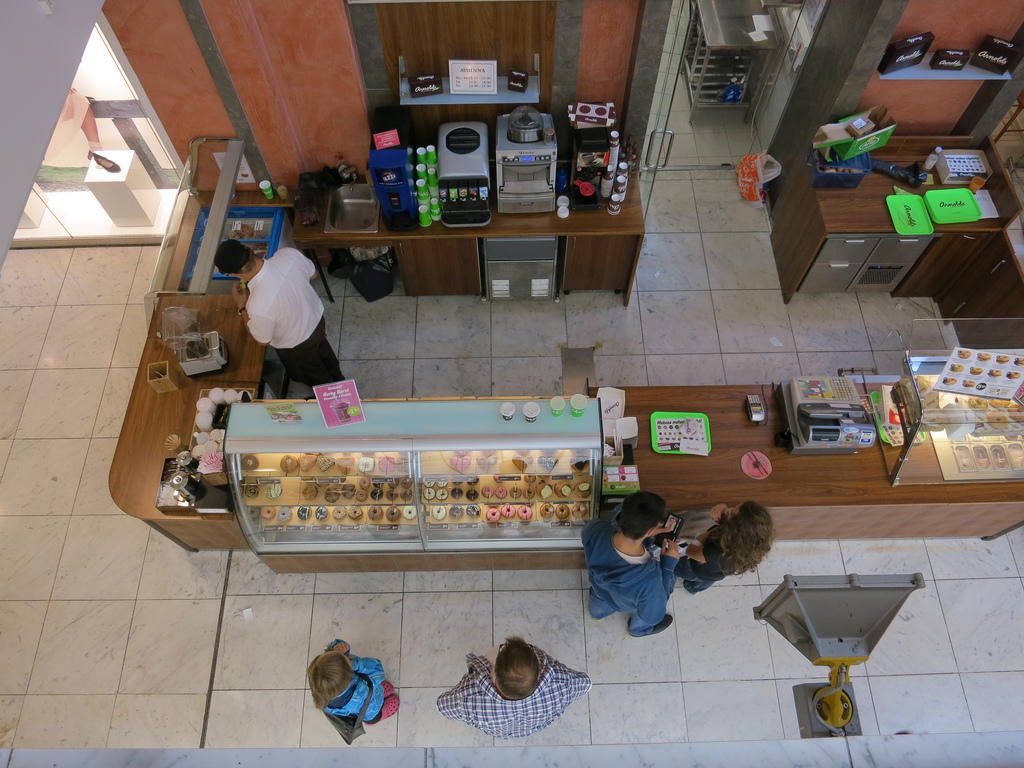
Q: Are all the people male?
A: No, they are both male and female.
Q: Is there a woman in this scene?
A: Yes, there is a woman.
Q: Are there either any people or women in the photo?
A: Yes, there is a woman.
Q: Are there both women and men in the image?
A: Yes, there are both a woman and a man.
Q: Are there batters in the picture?
A: No, there are no batters.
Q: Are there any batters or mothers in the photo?
A: No, there are no batters or mothers.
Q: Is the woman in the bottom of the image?
A: Yes, the woman is in the bottom of the image.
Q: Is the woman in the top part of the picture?
A: No, the woman is in the bottom of the image.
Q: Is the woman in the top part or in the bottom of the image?
A: The woman is in the bottom of the image.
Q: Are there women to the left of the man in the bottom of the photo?
A: Yes, there is a woman to the left of the man.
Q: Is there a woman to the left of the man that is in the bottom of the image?
A: Yes, there is a woman to the left of the man.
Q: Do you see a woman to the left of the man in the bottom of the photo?
A: Yes, there is a woman to the left of the man.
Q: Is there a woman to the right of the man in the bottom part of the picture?
A: No, the woman is to the left of the man.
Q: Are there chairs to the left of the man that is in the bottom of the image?
A: No, there is a woman to the left of the man.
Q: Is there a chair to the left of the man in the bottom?
A: No, there is a woman to the left of the man.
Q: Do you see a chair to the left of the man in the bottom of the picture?
A: No, there is a woman to the left of the man.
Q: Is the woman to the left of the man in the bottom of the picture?
A: Yes, the woman is to the left of the man.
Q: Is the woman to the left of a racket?
A: No, the woman is to the left of the man.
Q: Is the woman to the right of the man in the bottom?
A: No, the woman is to the left of the man.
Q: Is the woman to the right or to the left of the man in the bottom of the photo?
A: The woman is to the left of the man.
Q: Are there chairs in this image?
A: No, there are no chairs.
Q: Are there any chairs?
A: No, there are no chairs.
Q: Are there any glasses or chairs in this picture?
A: No, there are no chairs or glasses.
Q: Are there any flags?
A: No, there are no flags.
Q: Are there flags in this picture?
A: No, there are no flags.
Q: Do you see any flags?
A: No, there are no flags.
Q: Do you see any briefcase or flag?
A: No, there are no flags or briefcases.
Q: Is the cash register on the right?
A: Yes, the cash register is on the right of the image.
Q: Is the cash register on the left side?
A: No, the cash register is on the right of the image.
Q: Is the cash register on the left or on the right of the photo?
A: The cash register is on the right of the image.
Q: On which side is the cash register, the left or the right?
A: The cash register is on the right of the image.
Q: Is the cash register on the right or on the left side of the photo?
A: The cash register is on the right of the image.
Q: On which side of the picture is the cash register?
A: The cash register is on the right of the image.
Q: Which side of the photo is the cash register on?
A: The cash register is on the right of the image.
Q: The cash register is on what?
A: The cash register is on the counter.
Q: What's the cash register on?
A: The cash register is on the counter.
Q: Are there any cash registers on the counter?
A: Yes, there is a cash register on the counter.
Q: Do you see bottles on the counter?
A: No, there is a cash register on the counter.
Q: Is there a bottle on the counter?
A: No, there is a cash register on the counter.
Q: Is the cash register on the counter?
A: Yes, the cash register is on the counter.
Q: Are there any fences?
A: No, there are no fences.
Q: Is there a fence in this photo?
A: No, there are no fences.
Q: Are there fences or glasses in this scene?
A: No, there are no fences or glasses.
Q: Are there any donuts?
A: Yes, there are donuts.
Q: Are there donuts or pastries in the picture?
A: Yes, there are donuts.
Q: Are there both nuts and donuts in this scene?
A: No, there are donuts but no nuts.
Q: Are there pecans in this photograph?
A: No, there are no pecans.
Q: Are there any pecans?
A: No, there are no pecans.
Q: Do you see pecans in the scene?
A: No, there are no pecans.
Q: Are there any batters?
A: No, there are no batters.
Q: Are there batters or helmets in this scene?
A: No, there are no batters or helmets.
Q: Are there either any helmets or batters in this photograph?
A: No, there are no batters or helmets.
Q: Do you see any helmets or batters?
A: No, there are no batters or helmets.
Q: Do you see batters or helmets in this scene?
A: No, there are no batters or helmets.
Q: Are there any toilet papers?
A: No, there are no toilet papers.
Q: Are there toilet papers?
A: No, there are no toilet papers.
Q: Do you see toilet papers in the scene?
A: No, there are no toilet papers.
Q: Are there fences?
A: No, there are no fences.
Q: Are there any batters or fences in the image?
A: No, there are no fences or batters.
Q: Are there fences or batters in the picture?
A: No, there are no fences or batters.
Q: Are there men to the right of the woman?
A: Yes, there is a man to the right of the woman.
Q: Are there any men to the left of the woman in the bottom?
A: No, the man is to the right of the woman.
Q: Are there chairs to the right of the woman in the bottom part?
A: No, there is a man to the right of the woman.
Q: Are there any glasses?
A: No, there are no glasses.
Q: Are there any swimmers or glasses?
A: No, there are no glasses or swimmers.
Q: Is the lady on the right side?
A: Yes, the lady is on the right of the image.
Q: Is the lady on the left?
A: No, the lady is on the right of the image.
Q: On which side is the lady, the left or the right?
A: The lady is on the right of the image.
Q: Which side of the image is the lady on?
A: The lady is on the right of the image.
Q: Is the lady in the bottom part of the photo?
A: Yes, the lady is in the bottom of the image.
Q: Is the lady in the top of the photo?
A: No, the lady is in the bottom of the image.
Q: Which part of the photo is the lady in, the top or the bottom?
A: The lady is in the bottom of the image.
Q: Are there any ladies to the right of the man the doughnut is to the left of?
A: Yes, there is a lady to the right of the man.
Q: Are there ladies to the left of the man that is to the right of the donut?
A: No, the lady is to the right of the man.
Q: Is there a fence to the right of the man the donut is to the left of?
A: No, there is a lady to the right of the man.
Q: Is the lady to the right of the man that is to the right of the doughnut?
A: Yes, the lady is to the right of the man.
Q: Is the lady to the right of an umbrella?
A: No, the lady is to the right of the man.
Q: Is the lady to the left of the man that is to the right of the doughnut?
A: No, the lady is to the right of the man.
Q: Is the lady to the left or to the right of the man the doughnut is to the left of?
A: The lady is to the right of the man.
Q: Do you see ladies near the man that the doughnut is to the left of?
A: Yes, there is a lady near the man.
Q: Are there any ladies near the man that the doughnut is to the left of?
A: Yes, there is a lady near the man.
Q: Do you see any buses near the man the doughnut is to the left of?
A: No, there is a lady near the man.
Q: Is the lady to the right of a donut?
A: Yes, the lady is to the right of a donut.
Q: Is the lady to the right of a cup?
A: No, the lady is to the right of a donut.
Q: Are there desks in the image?
A: Yes, there is a desk.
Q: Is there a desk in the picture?
A: Yes, there is a desk.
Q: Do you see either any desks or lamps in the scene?
A: Yes, there is a desk.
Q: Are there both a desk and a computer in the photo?
A: No, there is a desk but no computers.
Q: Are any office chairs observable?
A: No, there are no office chairs.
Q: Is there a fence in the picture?
A: No, there are no fences.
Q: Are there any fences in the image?
A: No, there are no fences.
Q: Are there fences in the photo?
A: No, there are no fences.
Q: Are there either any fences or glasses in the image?
A: No, there are no fences or glasses.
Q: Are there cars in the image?
A: No, there are no cars.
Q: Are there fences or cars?
A: No, there are no cars or fences.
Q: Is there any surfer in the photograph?
A: No, there are no surfers.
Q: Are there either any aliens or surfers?
A: No, there are no surfers or aliens.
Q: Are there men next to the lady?
A: Yes, there is a man next to the lady.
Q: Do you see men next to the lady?
A: Yes, there is a man next to the lady.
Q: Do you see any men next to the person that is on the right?
A: Yes, there is a man next to the lady.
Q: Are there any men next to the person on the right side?
A: Yes, there is a man next to the lady.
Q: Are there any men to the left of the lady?
A: Yes, there is a man to the left of the lady.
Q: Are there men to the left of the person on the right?
A: Yes, there is a man to the left of the lady.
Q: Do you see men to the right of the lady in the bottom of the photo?
A: No, the man is to the left of the lady.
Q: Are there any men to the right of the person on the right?
A: No, the man is to the left of the lady.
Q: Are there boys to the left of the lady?
A: No, there is a man to the left of the lady.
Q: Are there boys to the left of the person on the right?
A: No, there is a man to the left of the lady.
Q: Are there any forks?
A: No, there are no forks.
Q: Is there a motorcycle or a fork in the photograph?
A: No, there are no forks or motorcycles.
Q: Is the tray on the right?
A: Yes, the tray is on the right of the image.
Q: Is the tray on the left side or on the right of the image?
A: The tray is on the right of the image.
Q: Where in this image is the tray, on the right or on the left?
A: The tray is on the right of the image.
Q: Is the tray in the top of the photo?
A: Yes, the tray is in the top of the image.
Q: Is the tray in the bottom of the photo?
A: No, the tray is in the top of the image.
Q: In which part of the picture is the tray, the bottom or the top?
A: The tray is in the top of the image.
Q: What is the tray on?
A: The tray is on the desk.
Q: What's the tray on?
A: The tray is on the desk.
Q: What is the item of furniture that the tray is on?
A: The piece of furniture is a desk.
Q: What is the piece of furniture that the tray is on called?
A: The piece of furniture is a desk.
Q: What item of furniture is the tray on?
A: The tray is on the desk.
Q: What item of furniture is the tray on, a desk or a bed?
A: The tray is on a desk.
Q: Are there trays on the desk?
A: Yes, there is a tray on the desk.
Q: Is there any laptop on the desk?
A: No, there is a tray on the desk.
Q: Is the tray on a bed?
A: No, the tray is on the desk.